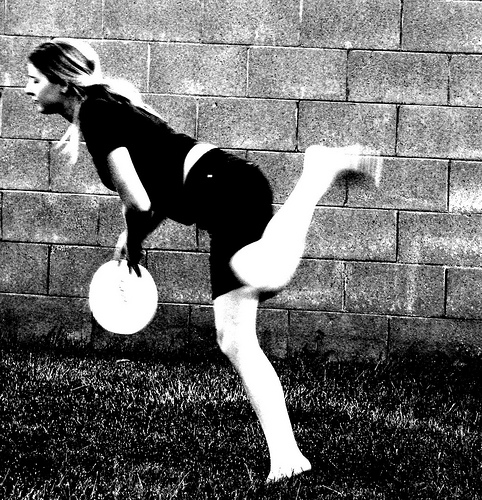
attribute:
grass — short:
[41, 356, 176, 494]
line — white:
[300, 347, 460, 452]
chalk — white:
[429, 92, 480, 264]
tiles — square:
[169, 30, 475, 111]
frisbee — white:
[90, 254, 157, 344]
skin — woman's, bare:
[221, 305, 316, 454]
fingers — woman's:
[105, 243, 142, 277]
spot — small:
[203, 163, 233, 186]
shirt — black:
[79, 83, 186, 186]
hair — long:
[37, 37, 106, 95]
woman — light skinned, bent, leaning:
[45, 46, 374, 375]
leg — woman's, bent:
[249, 148, 370, 311]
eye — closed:
[20, 68, 56, 90]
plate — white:
[81, 254, 154, 328]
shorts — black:
[178, 148, 270, 266]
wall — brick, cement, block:
[160, 32, 431, 186]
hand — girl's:
[102, 234, 151, 283]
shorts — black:
[172, 135, 286, 305]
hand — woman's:
[107, 230, 149, 275]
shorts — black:
[180, 144, 286, 297]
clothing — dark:
[80, 92, 271, 296]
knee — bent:
[238, 239, 303, 298]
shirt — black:
[83, 98, 199, 225]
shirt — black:
[67, 80, 194, 226]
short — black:
[179, 138, 280, 298]